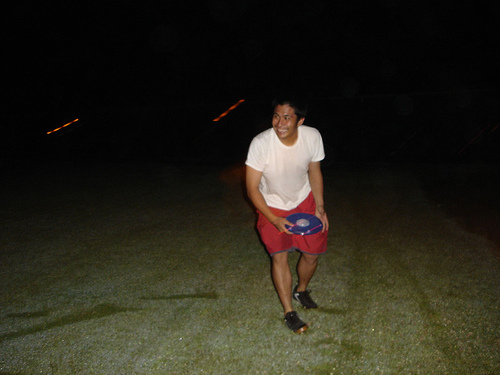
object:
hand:
[272, 214, 292, 232]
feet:
[283, 310, 309, 334]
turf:
[340, 332, 396, 356]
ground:
[102, 276, 263, 366]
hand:
[313, 208, 333, 234]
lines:
[108, 280, 350, 362]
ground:
[352, 160, 475, 360]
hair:
[272, 97, 306, 124]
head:
[272, 97, 305, 140]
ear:
[297, 118, 305, 127]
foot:
[293, 287, 319, 310]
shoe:
[285, 311, 310, 333]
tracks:
[61, 224, 443, 354]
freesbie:
[272, 209, 332, 236]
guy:
[245, 99, 332, 334]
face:
[272, 103, 298, 138]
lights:
[37, 112, 90, 135]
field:
[29, 60, 239, 310]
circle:
[296, 218, 310, 226]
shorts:
[257, 190, 329, 256]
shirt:
[246, 125, 326, 211]